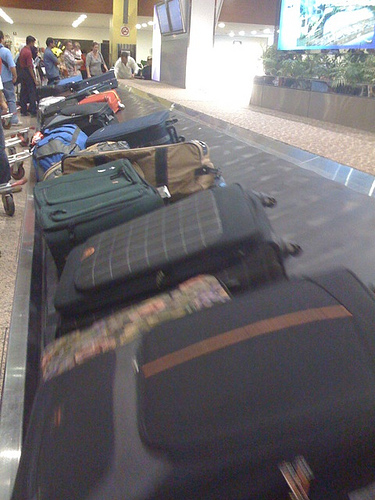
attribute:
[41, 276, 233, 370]
suitcase — floral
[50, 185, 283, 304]
suitcase — plaid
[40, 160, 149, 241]
suitcase — green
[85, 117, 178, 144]
suitcase — blue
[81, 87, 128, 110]
suitcase — orange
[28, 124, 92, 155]
duffle bag — blue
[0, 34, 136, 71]
people — group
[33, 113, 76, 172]
bag — blue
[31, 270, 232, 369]
suitcase — colorful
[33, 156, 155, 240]
suitcase — green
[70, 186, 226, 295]
pocket — plaid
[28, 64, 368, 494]
conveyor — moving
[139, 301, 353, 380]
stripe — brown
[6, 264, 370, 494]
suitcase — black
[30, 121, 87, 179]
bag — blue, duffel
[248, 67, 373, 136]
conveyor — luggage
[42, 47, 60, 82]
shirt — blue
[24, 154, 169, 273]
suitcase — green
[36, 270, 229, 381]
suitcase — flower covered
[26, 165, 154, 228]
green luggage — green 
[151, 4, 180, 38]
screen — wall mounted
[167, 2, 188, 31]
screen — wall mounted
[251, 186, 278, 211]
luggage wheel — black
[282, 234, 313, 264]
luggage wheel — black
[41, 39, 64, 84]
blue shirt — dark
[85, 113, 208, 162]
luggage — black colored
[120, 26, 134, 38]
sign — red and white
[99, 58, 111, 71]
handbag — black colored